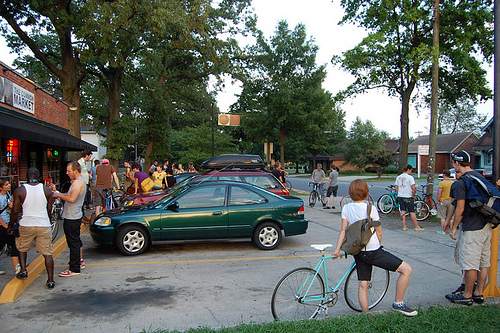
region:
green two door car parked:
[84, 175, 319, 252]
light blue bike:
[259, 226, 391, 313]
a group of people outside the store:
[2, 134, 207, 302]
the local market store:
[1, 56, 102, 253]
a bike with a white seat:
[295, 228, 357, 284]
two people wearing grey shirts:
[297, 153, 344, 203]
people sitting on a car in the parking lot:
[122, 162, 162, 207]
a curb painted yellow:
[5, 212, 106, 302]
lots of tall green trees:
[59, 8, 389, 180]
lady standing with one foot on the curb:
[342, 169, 439, 331]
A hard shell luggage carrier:
[196, 148, 279, 181]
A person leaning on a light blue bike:
[266, 179, 416, 321]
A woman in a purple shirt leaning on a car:
[122, 163, 163, 200]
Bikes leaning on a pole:
[385, 6, 443, 228]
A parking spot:
[2, 253, 399, 329]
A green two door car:
[90, 174, 303, 253]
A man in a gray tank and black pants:
[58, 160, 93, 277]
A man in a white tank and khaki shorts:
[13, 160, 65, 292]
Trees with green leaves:
[24, 0, 476, 151]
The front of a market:
[0, 61, 93, 283]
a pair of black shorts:
[342, 244, 407, 293]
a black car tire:
[242, 210, 289, 252]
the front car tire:
[120, 222, 159, 253]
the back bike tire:
[243, 248, 338, 330]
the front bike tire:
[345, 227, 394, 319]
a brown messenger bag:
[338, 184, 389, 261]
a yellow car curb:
[15, 210, 88, 304]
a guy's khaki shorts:
[451, 214, 498, 267]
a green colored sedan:
[99, 155, 308, 258]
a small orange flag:
[216, 104, 249, 130]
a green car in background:
[93, 175, 298, 252]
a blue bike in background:
[289, 254, 417, 313]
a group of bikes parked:
[315, 156, 452, 221]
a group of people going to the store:
[0, 155, 174, 282]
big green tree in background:
[351, 18, 480, 174]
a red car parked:
[124, 148, 314, 217]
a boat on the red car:
[153, 134, 321, 214]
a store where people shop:
[2, 58, 124, 289]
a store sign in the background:
[185, 106, 310, 191]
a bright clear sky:
[250, 8, 445, 143]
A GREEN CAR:
[88, 180, 313, 260]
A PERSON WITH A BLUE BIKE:
[270, 175, 422, 326]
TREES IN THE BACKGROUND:
[331, 3, 492, 193]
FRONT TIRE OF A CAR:
[107, 217, 165, 260]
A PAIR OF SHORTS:
[11, 221, 57, 258]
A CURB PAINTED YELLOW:
[0, 213, 80, 298]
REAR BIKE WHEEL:
[266, 263, 327, 326]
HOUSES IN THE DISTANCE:
[409, 119, 494, 184]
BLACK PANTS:
[59, 214, 92, 274]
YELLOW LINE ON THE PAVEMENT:
[58, 248, 346, 268]